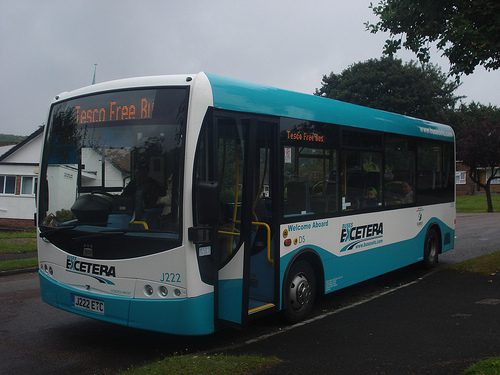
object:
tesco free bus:
[64, 87, 158, 127]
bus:
[33, 69, 459, 341]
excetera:
[62, 255, 118, 281]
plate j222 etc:
[70, 291, 108, 319]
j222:
[156, 271, 183, 286]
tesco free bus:
[285, 127, 326, 146]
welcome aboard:
[287, 219, 330, 233]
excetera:
[337, 217, 385, 253]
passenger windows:
[415, 133, 455, 204]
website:
[353, 237, 384, 250]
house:
[1, 110, 47, 232]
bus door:
[206, 102, 282, 332]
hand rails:
[220, 221, 243, 261]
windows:
[2, 170, 17, 195]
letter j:
[158, 269, 166, 284]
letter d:
[296, 233, 303, 246]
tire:
[280, 247, 328, 325]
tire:
[422, 223, 441, 274]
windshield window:
[34, 83, 195, 263]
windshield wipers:
[38, 222, 123, 238]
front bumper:
[31, 267, 216, 339]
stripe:
[276, 201, 458, 257]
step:
[248, 300, 277, 317]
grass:
[133, 341, 285, 375]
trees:
[444, 92, 500, 212]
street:
[1, 211, 499, 373]